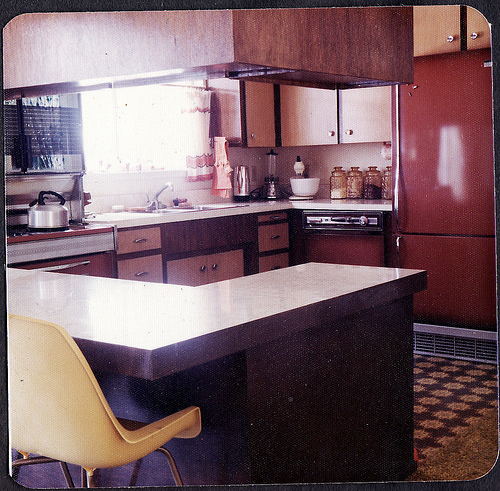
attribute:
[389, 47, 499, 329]
refrigerator freezer — dark, brown, paneled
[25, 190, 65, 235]
tea pot — silver, black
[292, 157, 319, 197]
mixing bowl — white, electric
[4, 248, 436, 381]
counter — empty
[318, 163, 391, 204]
container counter — glass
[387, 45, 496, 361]
fridge — red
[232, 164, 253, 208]
coffee pot — chrome